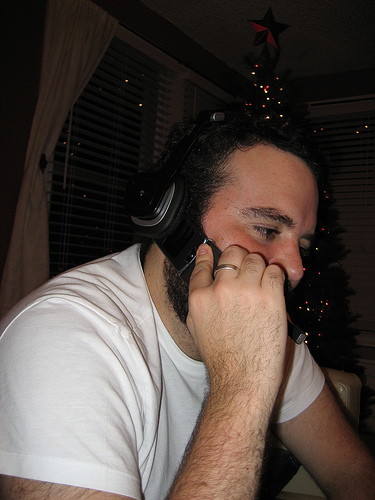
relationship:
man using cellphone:
[132, 118, 350, 473] [129, 188, 226, 301]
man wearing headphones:
[132, 118, 350, 473] [134, 115, 341, 233]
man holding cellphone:
[132, 118, 350, 473] [129, 188, 226, 301]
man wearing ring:
[132, 118, 350, 473] [213, 246, 246, 294]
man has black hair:
[132, 118, 350, 473] [178, 127, 292, 174]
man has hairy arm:
[132, 118, 350, 473] [206, 412, 267, 484]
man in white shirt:
[132, 118, 350, 473] [25, 284, 251, 482]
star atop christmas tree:
[249, 14, 298, 59] [254, 65, 279, 114]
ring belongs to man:
[213, 246, 246, 294] [132, 118, 350, 473]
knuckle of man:
[179, 282, 301, 326] [132, 118, 350, 473]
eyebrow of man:
[238, 193, 303, 234] [132, 118, 350, 473]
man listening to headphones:
[132, 118, 350, 473] [134, 115, 341, 233]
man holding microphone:
[132, 118, 350, 473] [284, 316, 319, 365]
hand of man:
[192, 243, 305, 396] [132, 118, 350, 473]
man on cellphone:
[132, 118, 350, 473] [129, 188, 226, 301]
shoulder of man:
[26, 262, 153, 407] [132, 118, 350, 473]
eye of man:
[243, 220, 303, 251] [132, 118, 350, 473]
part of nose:
[284, 245, 305, 287] [275, 251, 319, 280]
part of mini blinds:
[284, 245, 305, 287] [337, 114, 362, 161]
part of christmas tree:
[284, 245, 305, 287] [254, 65, 279, 114]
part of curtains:
[284, 245, 305, 287] [57, 32, 93, 85]